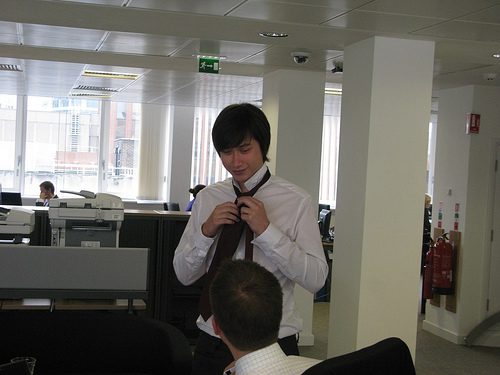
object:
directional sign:
[197, 57, 222, 74]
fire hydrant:
[421, 232, 459, 308]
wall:
[423, 86, 495, 342]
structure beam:
[336, 33, 426, 357]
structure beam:
[161, 93, 193, 218]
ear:
[209, 317, 219, 334]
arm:
[170, 206, 217, 292]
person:
[168, 93, 328, 354]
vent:
[66, 80, 119, 96]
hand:
[201, 195, 273, 232]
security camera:
[291, 50, 311, 66]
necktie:
[215, 179, 255, 261]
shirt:
[171, 177, 343, 277]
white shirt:
[171, 160, 329, 283]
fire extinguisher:
[426, 229, 460, 299]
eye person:
[194, 103, 296, 210]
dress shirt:
[175, 164, 304, 264]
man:
[181, 103, 312, 347]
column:
[337, 35, 426, 345]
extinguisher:
[421, 236, 459, 296]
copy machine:
[44, 193, 130, 245]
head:
[203, 260, 286, 357]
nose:
[228, 155, 245, 169]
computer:
[319, 206, 334, 239]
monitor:
[319, 204, 331, 236]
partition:
[3, 254, 203, 311]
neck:
[232, 332, 261, 374]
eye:
[236, 144, 256, 155]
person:
[165, 102, 333, 373]